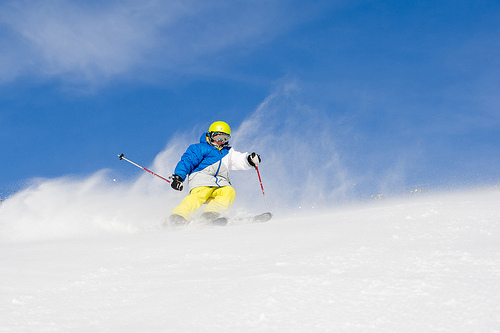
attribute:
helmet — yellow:
[207, 121, 230, 137]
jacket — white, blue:
[174, 141, 251, 189]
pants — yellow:
[175, 189, 238, 212]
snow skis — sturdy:
[137, 212, 280, 230]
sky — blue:
[1, 0, 497, 160]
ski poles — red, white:
[115, 157, 274, 203]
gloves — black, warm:
[162, 153, 265, 189]